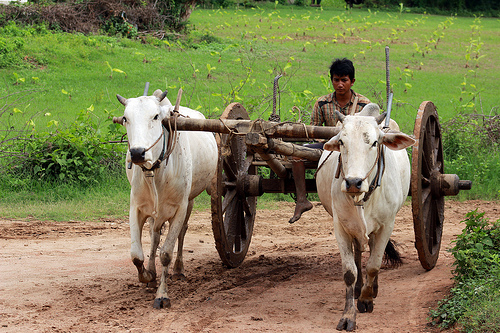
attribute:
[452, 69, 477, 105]
plant — green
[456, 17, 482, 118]
plant — red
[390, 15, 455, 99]
plant — red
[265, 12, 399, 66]
plant — red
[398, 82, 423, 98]
plant — green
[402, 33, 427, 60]
plant — green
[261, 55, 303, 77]
plant — green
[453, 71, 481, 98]
plant — green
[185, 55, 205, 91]
plant — green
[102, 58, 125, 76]
plant — green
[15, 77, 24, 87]
plant — green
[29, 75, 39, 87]
plant — green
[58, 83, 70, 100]
plant — green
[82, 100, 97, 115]
plant — green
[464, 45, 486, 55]
plant — green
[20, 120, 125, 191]
plant — green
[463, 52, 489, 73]
plant — green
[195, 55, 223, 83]
plant —  green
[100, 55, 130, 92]
plant — green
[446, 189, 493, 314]
plant — green